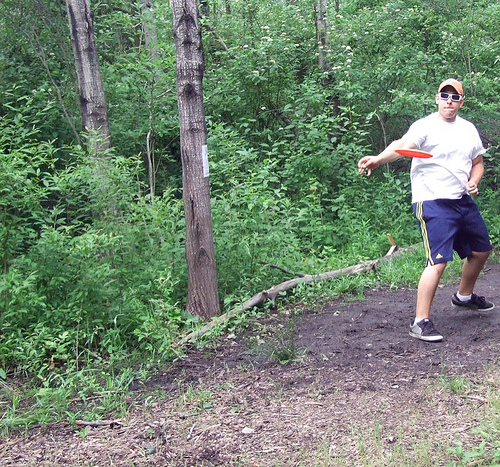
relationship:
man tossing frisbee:
[355, 76, 495, 343] [394, 146, 432, 161]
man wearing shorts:
[355, 76, 495, 343] [410, 188, 496, 267]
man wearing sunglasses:
[355, 76, 495, 343] [434, 90, 466, 103]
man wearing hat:
[355, 76, 495, 343] [431, 74, 466, 99]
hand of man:
[357, 155, 381, 177] [355, 76, 495, 343]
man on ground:
[340, 70, 497, 340] [3, 236, 499, 467]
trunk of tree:
[171, 6, 222, 323] [172, 0, 218, 325]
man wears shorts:
[355, 76, 495, 343] [405, 188, 491, 265]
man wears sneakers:
[355, 76, 495, 343] [391, 281, 494, 351]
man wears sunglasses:
[355, 76, 495, 343] [434, 87, 464, 102]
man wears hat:
[355, 76, 495, 343] [436, 74, 466, 101]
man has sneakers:
[355, 76, 495, 343] [404, 290, 499, 342]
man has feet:
[355, 76, 495, 343] [412, 294, 494, 341]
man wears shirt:
[355, 76, 495, 343] [404, 111, 488, 202]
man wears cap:
[355, 76, 495, 343] [433, 74, 465, 96]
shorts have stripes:
[409, 192, 494, 270] [415, 197, 434, 265]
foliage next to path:
[1, 3, 498, 460] [7, 261, 497, 465]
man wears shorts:
[355, 76, 495, 343] [403, 187, 498, 274]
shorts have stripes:
[403, 187, 498, 274] [399, 187, 436, 284]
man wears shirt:
[355, 76, 495, 343] [398, 107, 487, 206]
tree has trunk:
[119, 9, 276, 308] [167, 0, 221, 323]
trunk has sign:
[167, 0, 221, 323] [200, 141, 209, 181]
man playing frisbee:
[355, 76, 495, 343] [383, 142, 435, 160]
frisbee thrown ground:
[391, 145, 439, 159] [424, 147, 471, 197]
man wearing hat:
[355, 76, 495, 343] [424, 59, 473, 106]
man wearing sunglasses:
[355, 76, 495, 343] [411, 84, 482, 114]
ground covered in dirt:
[200, 267, 482, 461] [1, 259, 499, 464]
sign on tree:
[200, 140, 212, 177] [166, 1, 223, 316]